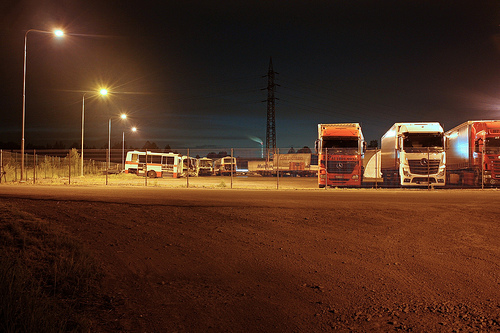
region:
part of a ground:
[212, 214, 279, 279]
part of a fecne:
[255, 134, 277, 188]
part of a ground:
[265, 247, 310, 316]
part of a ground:
[237, 256, 276, 316]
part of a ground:
[275, 230, 320, 296]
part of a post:
[316, 146, 331, 180]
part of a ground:
[265, 228, 302, 275]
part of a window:
[316, 109, 361, 166]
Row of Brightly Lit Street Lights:
[18, 23, 140, 187]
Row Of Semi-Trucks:
[315, 121, 497, 188]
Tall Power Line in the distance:
[255, 57, 284, 169]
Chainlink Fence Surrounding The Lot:
[4, 145, 498, 188]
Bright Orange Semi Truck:
[319, 124, 361, 188]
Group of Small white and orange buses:
[125, 149, 238, 179]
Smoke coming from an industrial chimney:
[249, 129, 267, 161]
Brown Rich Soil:
[0, 187, 497, 331]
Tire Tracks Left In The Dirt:
[368, 226, 452, 323]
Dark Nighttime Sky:
[0, 0, 497, 159]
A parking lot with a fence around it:
[0, 149, 496, 186]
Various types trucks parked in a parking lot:
[52, 119, 498, 184]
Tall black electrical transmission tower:
[257, 54, 282, 151]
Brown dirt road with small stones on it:
[4, 188, 492, 331]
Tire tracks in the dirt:
[335, 216, 442, 286]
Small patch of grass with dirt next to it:
[0, 207, 112, 329]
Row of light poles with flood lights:
[7, 23, 141, 185]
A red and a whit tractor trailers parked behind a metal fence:
[314, 120, 496, 185]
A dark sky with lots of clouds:
[5, 7, 485, 149]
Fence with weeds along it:
[2, 144, 97, 182]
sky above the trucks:
[306, 15, 412, 99]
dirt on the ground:
[261, 219, 372, 281]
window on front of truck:
[397, 130, 449, 161]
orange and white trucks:
[300, 118, 455, 193]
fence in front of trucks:
[211, 146, 313, 193]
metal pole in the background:
[239, 42, 303, 131]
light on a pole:
[82, 85, 118, 117]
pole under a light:
[67, 96, 99, 146]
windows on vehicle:
[134, 153, 175, 168]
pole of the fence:
[219, 138, 244, 196]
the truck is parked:
[309, 108, 378, 214]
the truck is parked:
[382, 113, 454, 215]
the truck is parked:
[452, 106, 498, 185]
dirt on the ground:
[307, 292, 418, 322]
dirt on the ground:
[376, 289, 449, 317]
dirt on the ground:
[194, 222, 249, 256]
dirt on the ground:
[299, 277, 387, 330]